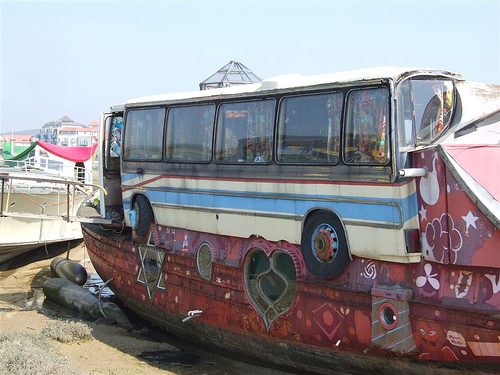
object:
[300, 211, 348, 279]
wheel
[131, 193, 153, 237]
wheel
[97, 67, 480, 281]
bus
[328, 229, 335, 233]
hole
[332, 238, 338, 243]
hole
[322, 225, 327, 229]
hole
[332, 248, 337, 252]
hole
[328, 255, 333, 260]
hole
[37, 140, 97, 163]
roof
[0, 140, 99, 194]
building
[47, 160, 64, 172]
window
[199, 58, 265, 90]
dome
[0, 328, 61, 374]
bush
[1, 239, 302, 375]
ground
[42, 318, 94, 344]
bush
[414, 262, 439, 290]
clover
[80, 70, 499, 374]
boat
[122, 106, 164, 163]
window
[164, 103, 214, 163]
window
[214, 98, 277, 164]
window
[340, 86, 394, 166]
window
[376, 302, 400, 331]
edge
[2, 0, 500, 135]
sky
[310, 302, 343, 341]
design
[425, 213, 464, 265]
design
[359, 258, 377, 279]
design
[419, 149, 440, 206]
design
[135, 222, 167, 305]
star of david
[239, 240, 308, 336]
heart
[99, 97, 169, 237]
front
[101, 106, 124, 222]
door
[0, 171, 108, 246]
walkway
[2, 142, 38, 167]
roof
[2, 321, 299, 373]
sand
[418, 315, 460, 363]
character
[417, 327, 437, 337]
eyes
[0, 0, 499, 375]
photo